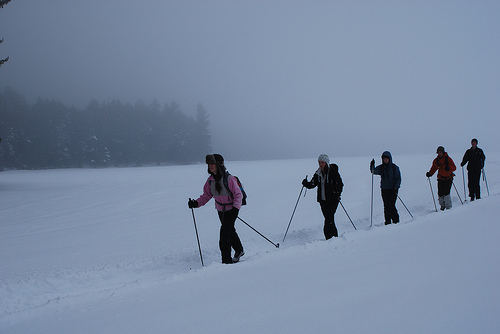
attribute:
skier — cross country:
[188, 153, 248, 265]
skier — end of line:
[460, 137, 486, 201]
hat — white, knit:
[317, 154, 330, 167]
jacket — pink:
[195, 174, 244, 212]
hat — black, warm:
[205, 153, 224, 165]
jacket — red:
[428, 153, 457, 178]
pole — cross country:
[188, 198, 206, 266]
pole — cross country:
[237, 215, 281, 247]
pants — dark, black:
[216, 209, 244, 263]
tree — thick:
[82, 98, 112, 167]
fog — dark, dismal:
[0, 0, 499, 170]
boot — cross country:
[233, 249, 246, 262]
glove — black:
[188, 199, 199, 209]